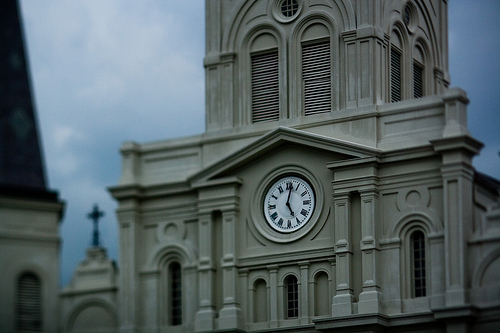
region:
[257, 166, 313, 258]
the clock is white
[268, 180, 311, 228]
the numbers are roman numerals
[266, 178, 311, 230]
the numbers are black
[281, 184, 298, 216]
the hands are black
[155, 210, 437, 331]
the windows are arches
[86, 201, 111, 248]
the cross is black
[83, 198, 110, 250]
the cross is on top of the building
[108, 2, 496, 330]
the building is light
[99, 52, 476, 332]
the building is tall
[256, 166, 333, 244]
the building has a clock on it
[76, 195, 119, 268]
THE CROSS IS BLURRY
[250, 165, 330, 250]
TIME IS AFTER 5:00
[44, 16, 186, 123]
CLOUDS ARE IN THE SKY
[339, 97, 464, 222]
THE BUILDING IS TAN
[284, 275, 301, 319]
PANES IN THE WINDOWS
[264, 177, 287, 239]
THE BACKGROUND IS WHITE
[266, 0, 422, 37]
TWO WINDOWS ARE ROUND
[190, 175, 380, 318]
FOUR COLUMNS ARE SHOWN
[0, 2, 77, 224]
THE STEEPLE IS BLACK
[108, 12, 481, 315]
THIS BUILDING IS A CHURCH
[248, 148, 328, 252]
Clock on the building to show the time.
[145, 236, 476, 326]
Many windows on the building.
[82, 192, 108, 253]
The Holy Cross.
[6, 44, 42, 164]
Diamond shapes on the roof.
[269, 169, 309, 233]
Roman numerals.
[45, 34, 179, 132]
Blue and cloudy sky above.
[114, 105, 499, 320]
Great architecture.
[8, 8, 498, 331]
Church building.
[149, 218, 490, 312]
Dark, unlit windows.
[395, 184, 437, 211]
Circle designs on the building.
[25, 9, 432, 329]
fancy building with clock tower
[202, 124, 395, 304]
giant clock on front of building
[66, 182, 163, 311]
church in background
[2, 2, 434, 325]
old church architecture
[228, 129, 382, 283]
just past 5:00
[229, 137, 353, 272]
clock face with roman numerals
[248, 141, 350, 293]
a couple minutes past five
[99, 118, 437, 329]
european church building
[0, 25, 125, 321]
chuch steeple in foreground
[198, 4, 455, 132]
windows at top of church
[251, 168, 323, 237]
round white and black clock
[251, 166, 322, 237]
white and black clock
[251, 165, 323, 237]
clock with roman numerals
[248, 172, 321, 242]
clock at 5:01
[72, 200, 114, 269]
cross at top of building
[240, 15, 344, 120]
arched windows with blinds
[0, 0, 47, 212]
steeple on top of building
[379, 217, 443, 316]
multiple arched window decoration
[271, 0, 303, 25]
small round window with grate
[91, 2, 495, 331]
top of beige clocktower